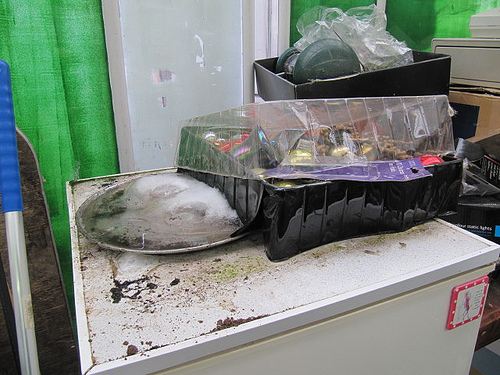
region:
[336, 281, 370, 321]
edge of a fridge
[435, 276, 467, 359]
part of a board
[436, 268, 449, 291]
;part of a line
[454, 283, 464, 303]
edge of a board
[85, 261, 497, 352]
dirty top of a refrigerator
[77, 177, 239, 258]
a dirty metal dish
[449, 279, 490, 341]
a red and white magnet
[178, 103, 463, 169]
clear plastic cover of flimsy plastic container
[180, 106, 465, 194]
plastic container with items in it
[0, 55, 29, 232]
blue handle on a pole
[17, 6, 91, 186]
green curtain hanging up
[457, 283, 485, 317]
a magnet with writing on it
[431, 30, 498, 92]
a cash register drawer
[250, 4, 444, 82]
items in a black box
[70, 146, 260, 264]
trey of food on table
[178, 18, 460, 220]
trash on top of table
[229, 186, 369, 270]
black plastic containter on tp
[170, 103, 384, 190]
see through plastic covering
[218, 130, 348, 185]
trash inside of plastic container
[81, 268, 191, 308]
dirt on top of white surface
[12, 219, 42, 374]
silver metal pole to tool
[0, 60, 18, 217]
blue grip handle of object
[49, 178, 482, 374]
small white freezer in room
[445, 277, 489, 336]
small red clock on side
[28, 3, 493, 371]
a picture of trash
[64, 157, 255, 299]
silver plate full of fuzzy mold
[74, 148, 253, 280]
plate full of fuzzy mold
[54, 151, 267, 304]
black and white mold on a plate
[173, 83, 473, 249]
beat up box of ornaments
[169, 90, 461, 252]
broken plastic box of ornaments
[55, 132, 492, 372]
dirty freezer holding trash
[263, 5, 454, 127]
black box with platic in it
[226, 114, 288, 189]
a multicolored bell Christmas ornament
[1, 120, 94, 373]
brown skateboard agains a green wall